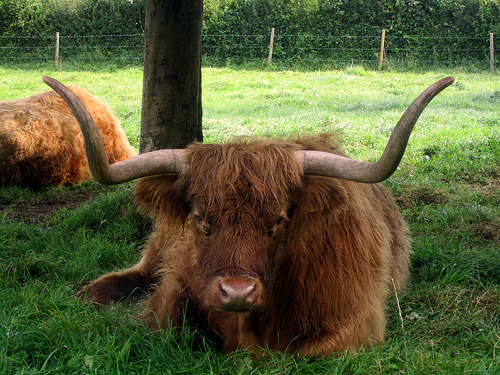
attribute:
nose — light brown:
[211, 273, 258, 302]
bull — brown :
[1, 83, 141, 187]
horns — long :
[37, 62, 459, 194]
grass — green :
[215, 74, 495, 151]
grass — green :
[402, 164, 498, 367]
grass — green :
[6, 204, 141, 368]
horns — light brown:
[293, 66, 448, 226]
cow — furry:
[42, 55, 452, 357]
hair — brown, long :
[105, 140, 405, 352]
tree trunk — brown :
[136, 7, 212, 157]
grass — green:
[256, 75, 368, 122]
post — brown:
[377, 28, 388, 71]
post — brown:
[264, 26, 279, 68]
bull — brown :
[44, 54, 461, 358]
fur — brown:
[300, 182, 381, 333]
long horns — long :
[32, 57, 467, 184]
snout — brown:
[201, 258, 271, 313]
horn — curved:
[265, 72, 480, 194]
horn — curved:
[33, 67, 202, 184]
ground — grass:
[1, 65, 497, 370]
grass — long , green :
[1, 33, 497, 371]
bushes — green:
[1, 0, 484, 60]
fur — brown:
[319, 223, 387, 294]